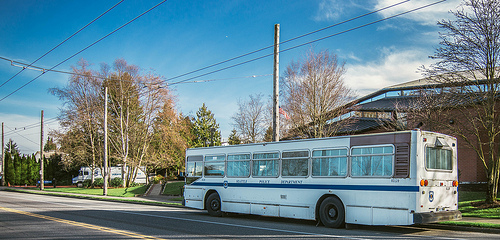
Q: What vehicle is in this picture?
A: Bus.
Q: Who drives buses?
A: Bus drivers.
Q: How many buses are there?
A: One.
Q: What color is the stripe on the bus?
A: Blue.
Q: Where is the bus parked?
A: Street.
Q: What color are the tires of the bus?
A: Black.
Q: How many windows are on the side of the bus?
A: Seven.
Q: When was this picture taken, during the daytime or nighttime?
A: Daytime.